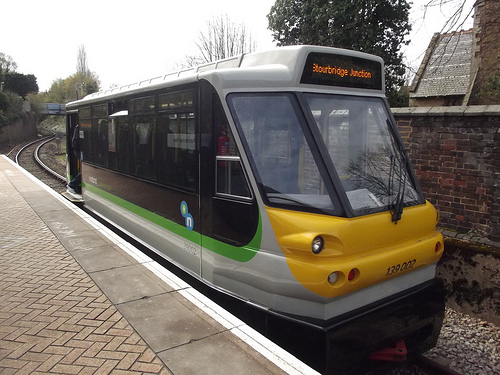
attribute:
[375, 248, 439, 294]
numbers — black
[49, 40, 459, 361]
train — yellow, white, short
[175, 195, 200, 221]
sign — blue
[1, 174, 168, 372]
brick — red